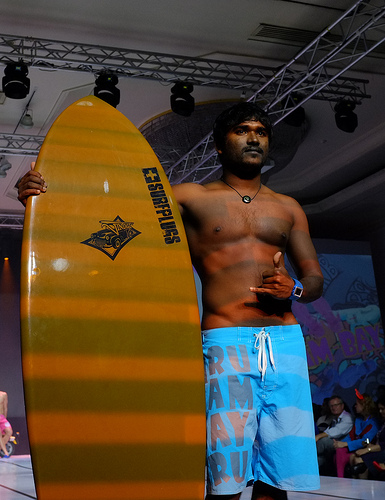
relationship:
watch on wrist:
[283, 276, 313, 307] [277, 276, 315, 306]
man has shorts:
[16, 104, 324, 499] [184, 316, 325, 492]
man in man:
[313, 392, 352, 456] [314, 392, 353, 469]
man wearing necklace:
[16, 104, 324, 499] [215, 173, 273, 209]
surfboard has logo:
[21, 94, 205, 499] [68, 211, 146, 271]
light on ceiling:
[326, 93, 369, 138] [0, 0, 384, 235]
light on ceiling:
[276, 89, 309, 132] [0, 0, 384, 235]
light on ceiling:
[158, 64, 206, 126] [0, 0, 384, 235]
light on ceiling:
[83, 65, 132, 125] [0, 0, 384, 235]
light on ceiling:
[0, 53, 44, 99] [0, 0, 384, 235]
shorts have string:
[184, 316, 325, 492] [248, 327, 280, 388]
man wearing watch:
[16, 104, 324, 499] [283, 276, 313, 307]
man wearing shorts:
[16, 104, 324, 499] [184, 316, 325, 492]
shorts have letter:
[184, 316, 325, 492] [224, 338, 254, 377]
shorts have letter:
[184, 316, 325, 492] [204, 340, 227, 379]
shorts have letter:
[184, 316, 325, 492] [221, 373, 260, 416]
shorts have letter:
[184, 316, 325, 492] [200, 374, 231, 414]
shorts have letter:
[184, 316, 325, 492] [217, 407, 256, 451]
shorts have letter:
[184, 316, 325, 492] [202, 410, 236, 456]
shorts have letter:
[184, 316, 325, 492] [222, 448, 254, 489]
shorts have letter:
[184, 316, 325, 492] [202, 447, 232, 494]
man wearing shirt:
[313, 392, 352, 456] [322, 411, 354, 440]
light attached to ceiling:
[0, 53, 34, 99] [0, 14, 368, 249]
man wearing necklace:
[16, 104, 324, 499] [216, 172, 263, 203]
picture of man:
[2, 2, 383, 498] [16, 104, 324, 499]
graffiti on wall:
[292, 258, 378, 453] [277, 237, 382, 450]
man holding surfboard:
[16, 104, 324, 499] [21, 94, 205, 499]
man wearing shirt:
[314, 392, 353, 469] [325, 410, 351, 433]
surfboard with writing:
[18, 94, 207, 499] [133, 155, 187, 268]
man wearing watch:
[16, 104, 324, 499] [289, 279, 302, 300]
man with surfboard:
[16, 104, 324, 499] [21, 94, 205, 499]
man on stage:
[16, 104, 324, 499] [0, 448, 383, 498]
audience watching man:
[294, 385, 384, 491] [16, 104, 324, 499]